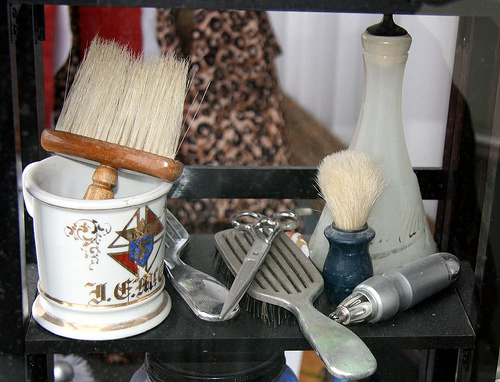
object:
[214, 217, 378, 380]
brush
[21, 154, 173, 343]
mug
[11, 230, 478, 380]
table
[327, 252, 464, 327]
hair trimmer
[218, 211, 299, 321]
scissor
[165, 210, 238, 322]
fork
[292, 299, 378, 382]
handle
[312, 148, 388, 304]
brush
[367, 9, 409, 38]
black top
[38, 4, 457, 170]
mirror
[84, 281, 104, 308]
gold writing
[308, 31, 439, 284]
bottle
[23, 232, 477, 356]
shelf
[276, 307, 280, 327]
bristle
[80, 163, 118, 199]
handle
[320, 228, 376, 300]
handle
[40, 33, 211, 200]
brush